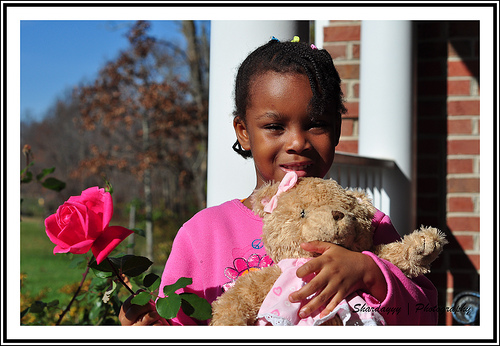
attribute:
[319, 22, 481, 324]
wall —  brick 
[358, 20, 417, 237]
column —  white,  two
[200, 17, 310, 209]
column —  white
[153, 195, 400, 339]
shirt —  girl's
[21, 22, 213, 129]
sky —  blue, blue, clear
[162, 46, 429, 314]
girl —  black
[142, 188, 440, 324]
shirt — pink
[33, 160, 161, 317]
pink rose —  pink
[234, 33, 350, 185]
head —  girl's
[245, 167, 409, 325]
bear —   teddy 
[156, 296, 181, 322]
leaf — green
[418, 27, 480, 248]
brown wall —  brown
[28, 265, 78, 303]
grass —  green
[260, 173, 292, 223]
bow — pink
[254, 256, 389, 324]
fabric —  pink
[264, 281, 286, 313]
hearts —  pink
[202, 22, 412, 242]
building — white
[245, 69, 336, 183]
face —  girl's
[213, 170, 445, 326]
bear —  teddy,    brown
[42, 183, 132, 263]
rose —  blooming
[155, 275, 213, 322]
leaves —  green